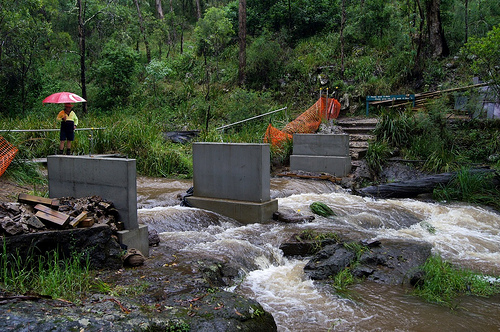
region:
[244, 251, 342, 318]
this is a body of water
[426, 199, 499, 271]
this is a body of water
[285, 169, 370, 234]
this is a body of water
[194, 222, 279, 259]
this is a body of water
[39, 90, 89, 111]
this is a body of water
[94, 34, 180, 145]
this is a green vegetation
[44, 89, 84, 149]
a person holding a umbrella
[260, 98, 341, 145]
a orange mesh fence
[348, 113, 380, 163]
a set of rock steps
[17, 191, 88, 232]
pieces of board on the ground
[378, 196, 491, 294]
white waves in the water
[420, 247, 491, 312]
green grass in the water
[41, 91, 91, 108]
a red and white umbrella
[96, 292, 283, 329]
a large flat rock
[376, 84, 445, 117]
several boards stacked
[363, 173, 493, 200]
a log on the ground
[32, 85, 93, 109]
open pink umbrella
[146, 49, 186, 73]
green leaves in brown trees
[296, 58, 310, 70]
green leaves in brown trees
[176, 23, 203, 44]
green leaves in brown trees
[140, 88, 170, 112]
green leaves in brown trees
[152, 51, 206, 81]
green leaves in brown trees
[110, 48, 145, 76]
green leaves in brown trees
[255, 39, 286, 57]
green leaves in brown trees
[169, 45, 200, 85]
green leaves in brown trees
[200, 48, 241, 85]
green leaves in brown trees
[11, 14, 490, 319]
stream running through heavy vegetation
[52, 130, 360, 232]
concrete supports across stream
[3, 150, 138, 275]
wood and debris against a support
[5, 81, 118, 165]
woman looking from platform on side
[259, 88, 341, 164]
red mesh screening leaning over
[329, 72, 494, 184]
railing and steps leading to stream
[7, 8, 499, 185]
slope of trees, plants and bushes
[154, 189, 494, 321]
curves of water along stream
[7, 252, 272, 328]
weed growing on top of flat rock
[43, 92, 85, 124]
woman holding open red umbrella over head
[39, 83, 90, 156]
the umbrella is pink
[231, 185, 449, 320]
stones in middle of the river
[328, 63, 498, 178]
stair going up the stairs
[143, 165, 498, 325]
the water is brown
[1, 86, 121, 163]
woman in front a fence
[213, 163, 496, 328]
a green grass in river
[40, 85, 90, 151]
THIS IS A PERSON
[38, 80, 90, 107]
THIS IS AN UMBRELLA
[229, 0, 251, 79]
THIS IS A TREE